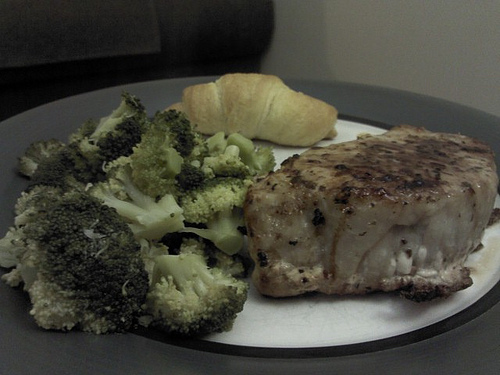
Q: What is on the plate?
A: Meat.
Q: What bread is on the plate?
A: Croissant.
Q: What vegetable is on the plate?
A: Broccoli.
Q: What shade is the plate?
A: White.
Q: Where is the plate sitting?
A: Table.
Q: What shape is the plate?
A: Round.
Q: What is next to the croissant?
A: Meat.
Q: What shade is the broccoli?
A: Green.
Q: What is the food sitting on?
A: Plate.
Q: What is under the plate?
A: Table.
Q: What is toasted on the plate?
A: Croissant.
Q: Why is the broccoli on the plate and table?
A: Plate is too small.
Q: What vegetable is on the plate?
A: Broccoli.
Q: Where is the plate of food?
A: A gray table.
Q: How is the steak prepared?
A: Grilled.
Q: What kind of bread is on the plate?
A: Croissant.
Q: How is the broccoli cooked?
A: Steamed.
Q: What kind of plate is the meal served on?
A: Styrofoam.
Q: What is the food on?
A: Plate.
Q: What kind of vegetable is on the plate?
A: Broccoli.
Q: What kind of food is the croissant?
A: Bread.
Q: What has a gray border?
A: Plate.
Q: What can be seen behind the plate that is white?
A: Wall.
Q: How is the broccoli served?
A: Cooked.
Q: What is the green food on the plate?
A: Broccoli.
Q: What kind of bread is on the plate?
A: Croissant.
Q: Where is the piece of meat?
A: On a white plate.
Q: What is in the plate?
A: Food.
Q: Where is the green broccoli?
A: In the plate.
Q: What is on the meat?
A: Pepper.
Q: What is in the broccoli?
A: Florets.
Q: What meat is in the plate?
A: A slice of boneless pork.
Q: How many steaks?
A: 1.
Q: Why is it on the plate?
A: To eat.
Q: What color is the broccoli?
A: Green.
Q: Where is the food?
A: On the plate.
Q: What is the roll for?
A: To eat.